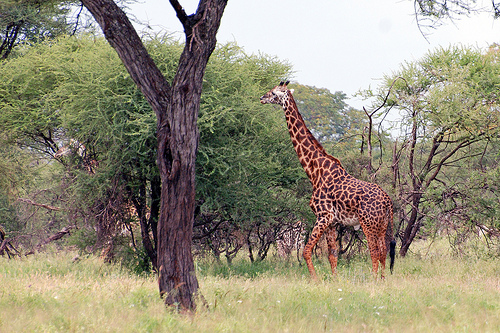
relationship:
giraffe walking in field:
[257, 76, 399, 288] [1, 236, 500, 333]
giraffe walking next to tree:
[257, 76, 399, 288] [376, 42, 500, 268]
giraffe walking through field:
[257, 76, 399, 288] [1, 236, 500, 333]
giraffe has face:
[257, 76, 399, 288] [260, 85, 281, 108]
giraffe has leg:
[257, 76, 399, 288] [299, 210, 334, 279]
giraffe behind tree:
[53, 132, 155, 269] [2, 32, 316, 268]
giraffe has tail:
[257, 76, 399, 288] [385, 197, 402, 279]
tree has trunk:
[376, 42, 500, 268] [394, 104, 452, 261]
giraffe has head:
[257, 76, 399, 288] [256, 77, 296, 108]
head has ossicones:
[256, 77, 296, 108] [278, 78, 288, 91]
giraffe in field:
[257, 76, 399, 288] [1, 236, 500, 333]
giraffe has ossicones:
[257, 76, 399, 288] [278, 78, 288, 91]